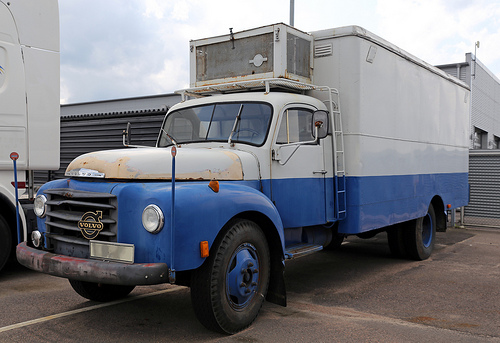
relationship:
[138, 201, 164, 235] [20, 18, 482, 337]
light on truck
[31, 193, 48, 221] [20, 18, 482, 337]
light on truck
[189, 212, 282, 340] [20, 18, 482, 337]
tire on truck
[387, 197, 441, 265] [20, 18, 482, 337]
tire on truck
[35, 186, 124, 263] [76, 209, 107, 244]
grid has emblem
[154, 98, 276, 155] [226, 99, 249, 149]
windows with wipers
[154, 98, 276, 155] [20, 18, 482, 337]
windows on truck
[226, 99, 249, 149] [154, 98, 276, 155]
wipers on windows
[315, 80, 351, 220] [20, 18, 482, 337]
ladder on truck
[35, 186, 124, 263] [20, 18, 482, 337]
grid on truck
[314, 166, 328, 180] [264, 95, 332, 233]
handle on door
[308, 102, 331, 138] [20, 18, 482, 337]
mirror on truck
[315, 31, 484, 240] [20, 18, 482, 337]
side of truck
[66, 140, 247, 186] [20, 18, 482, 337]
hood of truck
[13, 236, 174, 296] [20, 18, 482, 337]
bumper on truck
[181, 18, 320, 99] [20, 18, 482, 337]
unit top truck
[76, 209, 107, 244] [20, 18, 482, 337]
emblem on truck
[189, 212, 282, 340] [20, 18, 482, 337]
tire of truck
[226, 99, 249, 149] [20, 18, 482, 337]
wipers on truck